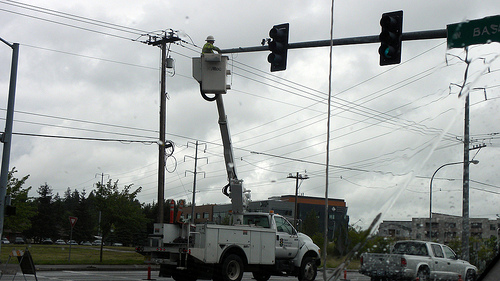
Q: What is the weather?
A: Cloudy.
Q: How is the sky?
A: Gray, dark and cloudy.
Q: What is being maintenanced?
A: A traffic light.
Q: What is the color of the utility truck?
A: White.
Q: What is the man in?
A: A man basket.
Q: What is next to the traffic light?
A: Telephone poles and wires.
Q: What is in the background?
A: Trees.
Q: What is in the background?
A: Buildings.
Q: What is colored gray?
A: The truck.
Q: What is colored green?
A: Trees.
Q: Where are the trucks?
A: In the street.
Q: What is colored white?
A: Truck.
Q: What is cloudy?
A: The sky.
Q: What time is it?
A: Afternoon.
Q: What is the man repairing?
A: Stop light.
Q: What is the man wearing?
A: Helmet.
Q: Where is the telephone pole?
A: Near the street light.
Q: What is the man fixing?
A: Traffic light.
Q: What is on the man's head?
A: Hard Hat.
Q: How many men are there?
A: One.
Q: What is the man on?
A: Lift.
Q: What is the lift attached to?
A: Truck.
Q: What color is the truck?
A: White.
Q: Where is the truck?
A: Street.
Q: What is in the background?
A: Buildings.